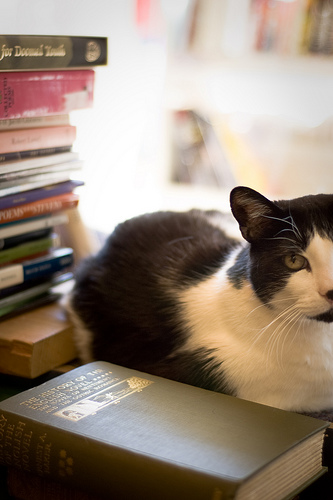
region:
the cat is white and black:
[80, 185, 332, 418]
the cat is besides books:
[0, 1, 332, 499]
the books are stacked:
[0, 36, 110, 320]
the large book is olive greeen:
[3, 359, 327, 496]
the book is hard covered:
[0, 359, 329, 497]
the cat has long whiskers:
[240, 296, 313, 371]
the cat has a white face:
[269, 235, 330, 319]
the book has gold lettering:
[27, 366, 153, 425]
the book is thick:
[232, 428, 327, 497]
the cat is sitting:
[79, 187, 332, 416]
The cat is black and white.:
[67, 183, 331, 418]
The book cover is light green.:
[0, 359, 327, 498]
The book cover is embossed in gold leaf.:
[18, 365, 155, 423]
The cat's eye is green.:
[281, 248, 314, 274]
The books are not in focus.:
[0, 32, 109, 379]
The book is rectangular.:
[4, 358, 331, 498]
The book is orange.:
[0, 192, 80, 221]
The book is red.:
[0, 66, 96, 122]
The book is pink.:
[0, 123, 77, 153]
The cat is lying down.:
[68, 185, 331, 415]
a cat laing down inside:
[93, 165, 328, 420]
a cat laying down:
[67, 180, 330, 396]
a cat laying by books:
[21, 136, 321, 413]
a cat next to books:
[38, 170, 328, 468]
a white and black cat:
[56, 178, 330, 450]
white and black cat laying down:
[39, 170, 328, 429]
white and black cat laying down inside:
[36, 172, 330, 459]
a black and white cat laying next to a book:
[40, 160, 323, 478]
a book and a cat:
[48, 216, 330, 484]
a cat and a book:
[24, 201, 292, 491]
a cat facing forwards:
[76, 178, 330, 398]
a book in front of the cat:
[0, 356, 332, 492]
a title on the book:
[16, 364, 162, 429]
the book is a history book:
[0, 341, 332, 496]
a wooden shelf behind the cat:
[2, 303, 92, 378]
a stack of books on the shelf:
[0, 33, 110, 327]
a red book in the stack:
[0, 65, 99, 129]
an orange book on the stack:
[0, 194, 83, 226]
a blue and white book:
[2, 246, 80, 292]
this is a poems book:
[0, 192, 80, 227]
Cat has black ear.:
[233, 178, 284, 249]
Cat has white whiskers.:
[264, 281, 303, 369]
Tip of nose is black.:
[319, 285, 332, 305]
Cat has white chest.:
[287, 329, 328, 378]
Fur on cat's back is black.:
[133, 207, 180, 258]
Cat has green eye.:
[274, 253, 317, 283]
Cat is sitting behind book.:
[178, 333, 324, 430]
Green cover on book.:
[93, 374, 242, 480]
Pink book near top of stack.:
[10, 72, 115, 103]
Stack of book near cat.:
[6, 34, 93, 284]